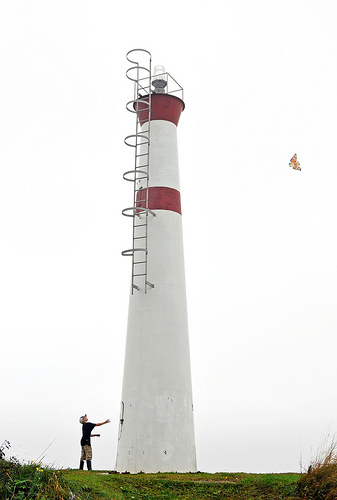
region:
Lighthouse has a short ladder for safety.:
[98, 43, 199, 496]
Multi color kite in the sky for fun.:
[284, 150, 307, 174]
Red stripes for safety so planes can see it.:
[96, 46, 201, 487]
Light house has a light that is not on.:
[89, 47, 212, 493]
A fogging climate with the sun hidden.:
[19, 13, 304, 488]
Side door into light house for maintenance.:
[93, 44, 218, 497]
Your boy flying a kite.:
[69, 409, 115, 472]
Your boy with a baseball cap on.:
[71, 411, 112, 473]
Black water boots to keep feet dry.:
[71, 408, 113, 470]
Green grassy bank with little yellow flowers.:
[6, 450, 331, 495]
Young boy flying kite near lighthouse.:
[79, 413, 109, 469]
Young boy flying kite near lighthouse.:
[114, 48, 197, 472]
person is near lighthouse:
[73, 411, 106, 467]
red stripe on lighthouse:
[127, 175, 184, 228]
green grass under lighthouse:
[80, 466, 266, 496]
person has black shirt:
[66, 410, 104, 448]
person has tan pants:
[78, 442, 100, 465]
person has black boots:
[76, 455, 100, 472]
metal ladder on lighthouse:
[114, 66, 182, 317]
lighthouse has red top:
[130, 92, 191, 131]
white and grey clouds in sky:
[24, 60, 109, 200]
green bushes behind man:
[4, 454, 59, 494]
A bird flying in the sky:
[284, 150, 306, 173]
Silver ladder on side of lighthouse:
[116, 44, 154, 297]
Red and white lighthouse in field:
[112, 45, 206, 472]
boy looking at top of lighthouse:
[59, 399, 110, 468]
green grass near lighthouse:
[77, 474, 301, 498]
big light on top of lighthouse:
[147, 59, 172, 92]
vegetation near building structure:
[1, 438, 59, 499]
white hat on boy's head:
[77, 411, 87, 421]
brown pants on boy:
[77, 442, 92, 463]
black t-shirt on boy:
[76, 421, 99, 444]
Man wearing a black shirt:
[75, 408, 113, 470]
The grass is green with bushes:
[15, 461, 319, 497]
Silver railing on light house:
[121, 46, 154, 294]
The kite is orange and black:
[280, 148, 308, 181]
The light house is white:
[110, 71, 211, 477]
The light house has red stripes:
[128, 95, 191, 212]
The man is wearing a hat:
[76, 412, 112, 473]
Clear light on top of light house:
[149, 62, 171, 90]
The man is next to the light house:
[75, 45, 204, 473]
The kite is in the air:
[282, 148, 309, 171]